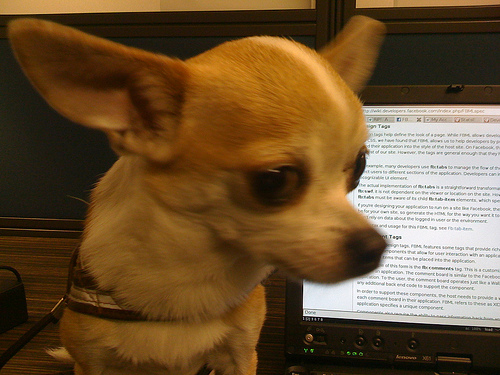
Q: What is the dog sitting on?
A: Table.